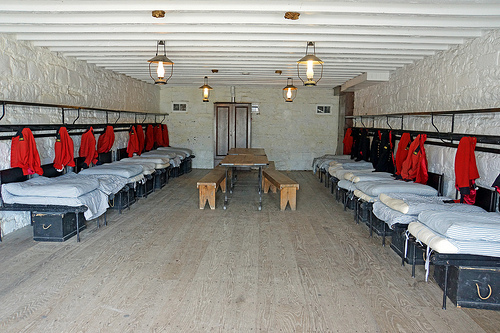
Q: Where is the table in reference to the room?
A: Middle.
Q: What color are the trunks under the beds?
A: Black.